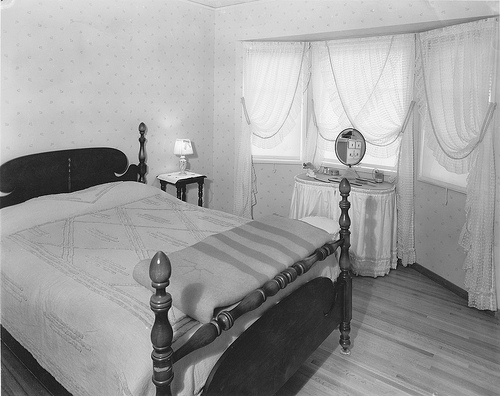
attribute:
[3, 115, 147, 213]
head board — dark brown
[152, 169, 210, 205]
side table — dark brown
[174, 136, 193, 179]
white lamp — small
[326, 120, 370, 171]
oval mirror — large , oval 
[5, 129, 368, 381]
bed — large, wooden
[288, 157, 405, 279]
table skirt — large, white, on a table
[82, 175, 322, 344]
comforter — on the bed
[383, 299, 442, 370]
floor — wooden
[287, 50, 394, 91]
curtains — white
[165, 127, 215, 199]
lamp — small , on the night stand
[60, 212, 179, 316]
sheet — folded, on the bed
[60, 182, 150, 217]
pillow — white , on bed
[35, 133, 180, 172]
bed head — large, black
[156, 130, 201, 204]
lamp — small, white, on table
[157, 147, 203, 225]
bedside table — black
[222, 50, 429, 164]
valance — sheer, white, on window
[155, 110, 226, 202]
portrayal — of lamp, white , Black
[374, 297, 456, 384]
floor — Wooden, with grains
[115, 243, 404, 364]
foot board — Wooden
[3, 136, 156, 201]
head rest — Wooden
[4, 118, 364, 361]
bed — with white sheets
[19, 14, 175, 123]
design — simple, wallpaper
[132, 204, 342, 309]
comforter — striped 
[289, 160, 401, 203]
table — oval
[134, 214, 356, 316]
blanket — folded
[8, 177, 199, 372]
cover — white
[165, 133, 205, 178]
lamp — small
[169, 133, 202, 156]
shade — white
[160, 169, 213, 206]
table — small, wood, square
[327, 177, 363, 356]
post — wood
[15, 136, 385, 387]
bed — queen size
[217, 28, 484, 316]
curtains — white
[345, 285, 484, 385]
wood — hard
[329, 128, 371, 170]
mirror — small, vanity, round, circle shape